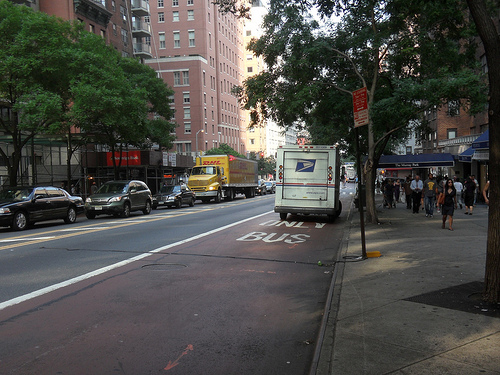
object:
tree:
[107, 53, 177, 196]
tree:
[50, 20, 176, 197]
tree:
[2, 0, 178, 192]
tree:
[238, 3, 497, 225]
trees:
[197, 142, 241, 158]